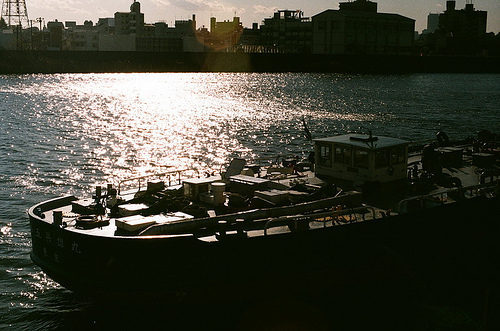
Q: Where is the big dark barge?
A: On the water.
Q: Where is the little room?
A: On top of the long flat boat.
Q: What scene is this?
A: Lake scene.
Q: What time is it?
A: Sunrise.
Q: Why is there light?
A: From the sun.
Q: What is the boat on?
A: The water.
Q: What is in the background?
A: Buildings.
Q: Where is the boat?
A: On the water.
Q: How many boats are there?
A: 1.